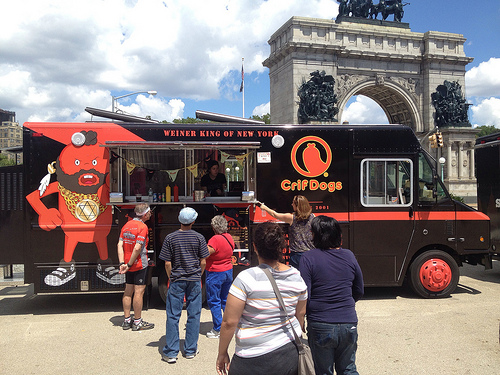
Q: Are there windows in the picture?
A: Yes, there is a window.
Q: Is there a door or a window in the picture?
A: Yes, there is a window.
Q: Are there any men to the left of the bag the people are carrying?
A: Yes, there is a man to the left of the bag.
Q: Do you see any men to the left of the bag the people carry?
A: Yes, there is a man to the left of the bag.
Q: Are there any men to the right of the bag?
A: No, the man is to the left of the bag.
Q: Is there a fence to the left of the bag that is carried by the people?
A: No, there is a man to the left of the bag.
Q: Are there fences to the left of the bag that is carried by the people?
A: No, there is a man to the left of the bag.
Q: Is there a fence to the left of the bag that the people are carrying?
A: No, there is a man to the left of the bag.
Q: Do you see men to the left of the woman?
A: Yes, there is a man to the left of the woman.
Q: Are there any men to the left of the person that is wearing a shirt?
A: Yes, there is a man to the left of the woman.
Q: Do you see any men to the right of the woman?
A: No, the man is to the left of the woman.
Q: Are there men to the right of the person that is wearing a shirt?
A: No, the man is to the left of the woman.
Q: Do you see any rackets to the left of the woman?
A: No, there is a man to the left of the woman.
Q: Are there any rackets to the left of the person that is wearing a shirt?
A: No, there is a man to the left of the woman.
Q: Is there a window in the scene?
A: Yes, there is a window.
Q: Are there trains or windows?
A: Yes, there is a window.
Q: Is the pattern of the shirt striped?
A: Yes, the shirt is striped.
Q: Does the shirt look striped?
A: Yes, the shirt is striped.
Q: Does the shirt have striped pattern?
A: Yes, the shirt is striped.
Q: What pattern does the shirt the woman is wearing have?
A: The shirt has striped pattern.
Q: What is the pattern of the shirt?
A: The shirt is striped.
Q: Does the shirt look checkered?
A: No, the shirt is striped.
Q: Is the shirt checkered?
A: No, the shirt is striped.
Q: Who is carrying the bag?
A: The people are carrying the bag.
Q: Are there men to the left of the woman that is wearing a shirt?
A: Yes, there is a man to the left of the woman.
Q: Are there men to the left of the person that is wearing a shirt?
A: Yes, there is a man to the left of the woman.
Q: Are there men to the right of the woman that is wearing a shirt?
A: No, the man is to the left of the woman.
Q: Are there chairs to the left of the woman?
A: No, there is a man to the left of the woman.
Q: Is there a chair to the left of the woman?
A: No, there is a man to the left of the woman.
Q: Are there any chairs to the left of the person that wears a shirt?
A: No, there is a man to the left of the woman.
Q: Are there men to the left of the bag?
A: Yes, there is a man to the left of the bag.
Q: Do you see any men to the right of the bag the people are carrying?
A: No, the man is to the left of the bag.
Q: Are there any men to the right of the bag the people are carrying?
A: No, the man is to the left of the bag.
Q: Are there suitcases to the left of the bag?
A: No, there is a man to the left of the bag.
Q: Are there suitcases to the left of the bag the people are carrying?
A: No, there is a man to the left of the bag.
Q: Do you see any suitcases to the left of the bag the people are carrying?
A: No, there is a man to the left of the bag.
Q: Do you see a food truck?
A: Yes, there is a food truck.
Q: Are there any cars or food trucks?
A: Yes, there is a food truck.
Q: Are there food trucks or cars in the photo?
A: Yes, there is a food truck.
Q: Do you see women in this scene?
A: Yes, there is a woman.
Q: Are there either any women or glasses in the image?
A: Yes, there is a woman.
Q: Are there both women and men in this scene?
A: Yes, there are both a woman and a man.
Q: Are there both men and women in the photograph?
A: Yes, there are both a woman and a man.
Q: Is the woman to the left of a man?
A: No, the woman is to the right of a man.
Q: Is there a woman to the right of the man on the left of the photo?
A: Yes, there is a woman to the right of the man.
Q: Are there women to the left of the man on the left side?
A: No, the woman is to the right of the man.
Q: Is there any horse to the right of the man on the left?
A: No, there is a woman to the right of the man.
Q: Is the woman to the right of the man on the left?
A: Yes, the woman is to the right of the man.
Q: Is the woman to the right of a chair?
A: No, the woman is to the right of the man.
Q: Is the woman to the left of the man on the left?
A: No, the woman is to the right of the man.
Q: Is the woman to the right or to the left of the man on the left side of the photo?
A: The woman is to the right of the man.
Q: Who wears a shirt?
A: The woman wears a shirt.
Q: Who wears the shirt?
A: The woman wears a shirt.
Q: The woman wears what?
A: The woman wears a shirt.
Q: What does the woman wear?
A: The woman wears a shirt.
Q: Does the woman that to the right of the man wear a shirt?
A: Yes, the woman wears a shirt.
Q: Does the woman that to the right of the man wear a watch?
A: No, the woman wears a shirt.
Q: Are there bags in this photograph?
A: Yes, there is a bag.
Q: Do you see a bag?
A: Yes, there is a bag.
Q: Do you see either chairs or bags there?
A: Yes, there is a bag.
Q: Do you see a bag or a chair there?
A: Yes, there is a bag.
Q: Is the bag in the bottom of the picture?
A: Yes, the bag is in the bottom of the image.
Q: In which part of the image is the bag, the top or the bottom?
A: The bag is in the bottom of the image.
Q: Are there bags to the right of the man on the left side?
A: Yes, there is a bag to the right of the man.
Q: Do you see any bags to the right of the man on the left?
A: Yes, there is a bag to the right of the man.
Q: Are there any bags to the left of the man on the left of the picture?
A: No, the bag is to the right of the man.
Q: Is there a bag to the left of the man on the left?
A: No, the bag is to the right of the man.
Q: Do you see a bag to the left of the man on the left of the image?
A: No, the bag is to the right of the man.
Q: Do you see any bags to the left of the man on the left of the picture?
A: No, the bag is to the right of the man.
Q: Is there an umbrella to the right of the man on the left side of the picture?
A: No, there is a bag to the right of the man.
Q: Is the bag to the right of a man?
A: Yes, the bag is to the right of a man.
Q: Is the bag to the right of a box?
A: No, the bag is to the right of a man.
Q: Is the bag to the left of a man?
A: No, the bag is to the right of a man.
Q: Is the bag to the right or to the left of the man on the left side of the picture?
A: The bag is to the right of the man.